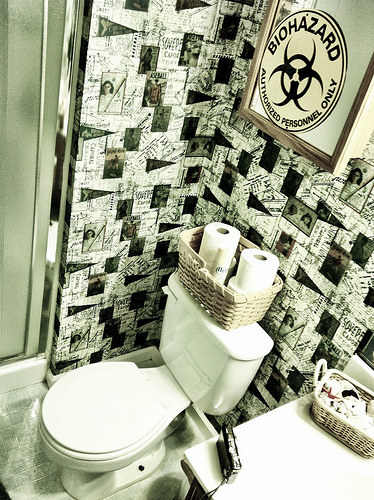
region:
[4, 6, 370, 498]
a toilet in the bathroom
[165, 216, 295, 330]
paper toilet in a basket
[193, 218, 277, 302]
white paper toilet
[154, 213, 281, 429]
a basket on top a tank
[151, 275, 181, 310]
handle of a tank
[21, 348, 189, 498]
toilet is close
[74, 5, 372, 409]
wall of bathroom is covered with paper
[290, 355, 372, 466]
small basket on a counter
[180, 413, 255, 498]
a camera on border of counter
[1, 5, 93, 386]
door of bathroom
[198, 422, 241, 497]
A camera sitting on the counter.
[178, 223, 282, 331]
Basket sitting on the back of a toilet.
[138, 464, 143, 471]
A bolt holding the commode down.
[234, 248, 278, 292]
Roll of toilet tissue.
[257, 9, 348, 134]
Giant biohazard picture with authorized personnel only written on it.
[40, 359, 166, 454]
Toilet seat lid that is in the down position.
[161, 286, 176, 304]
Handle to flush the commode with.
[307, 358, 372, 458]
Basket of various items on counter.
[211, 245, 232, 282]
Can of air freshener sitting in basket.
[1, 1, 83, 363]
Part of a glass shower door that is partially open.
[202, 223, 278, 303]
toilet paper rolls on back of toilet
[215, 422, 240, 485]
camera sitting on the counter top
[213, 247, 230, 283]
air freshener spray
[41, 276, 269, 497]
white toilet in the bathroom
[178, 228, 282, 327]
wicker basket on back of toilet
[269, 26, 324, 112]
black Biohazard symbol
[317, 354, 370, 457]
full wicker basket on counter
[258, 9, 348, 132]
biohazard symbol on the mirror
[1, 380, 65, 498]
tile in square pattern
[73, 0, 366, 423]
pattern on the wall paper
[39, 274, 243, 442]
white toilet in bathroom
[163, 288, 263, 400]
white toilet tank above bowl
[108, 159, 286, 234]
music flyers glued to wall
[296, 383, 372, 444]
white wicker basket on sink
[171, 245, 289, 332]
tan wicker basket on toilet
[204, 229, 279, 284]
white toilet paper rolls in basket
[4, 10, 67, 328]
glass sliding shower door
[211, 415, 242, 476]
black digital camera on sink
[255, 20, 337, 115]
round biohazard sticker on mirror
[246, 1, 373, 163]
square mirrored cabinet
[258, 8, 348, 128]
biohazard sign placed on bathroom medicine cabinet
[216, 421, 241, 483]
digital camera on bathroom counter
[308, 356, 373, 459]
basket with bathroom toiletries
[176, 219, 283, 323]
basket on toilet tank lid with bathroom supplies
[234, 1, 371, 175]
bathroom medicine cabinet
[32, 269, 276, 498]
white porcelain toilet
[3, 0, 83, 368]
shower stall with glass doors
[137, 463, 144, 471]
toilet retaining bolt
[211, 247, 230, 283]
can of aerosol air freshener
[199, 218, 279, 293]
rolls of toilet paper